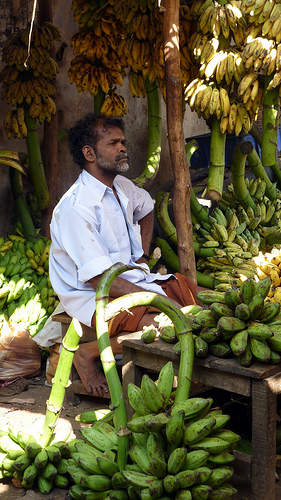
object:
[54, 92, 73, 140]
wall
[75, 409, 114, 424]
sandal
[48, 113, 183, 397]
man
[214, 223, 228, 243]
banana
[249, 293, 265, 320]
banana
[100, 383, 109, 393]
toes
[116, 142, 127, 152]
nose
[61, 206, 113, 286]
sleeves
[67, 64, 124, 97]
bunch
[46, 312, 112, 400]
stool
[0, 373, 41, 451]
ground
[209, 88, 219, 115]
banana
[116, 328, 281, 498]
table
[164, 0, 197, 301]
pole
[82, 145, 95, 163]
ear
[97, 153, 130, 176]
beard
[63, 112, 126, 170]
hair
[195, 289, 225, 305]
bananas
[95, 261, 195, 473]
stem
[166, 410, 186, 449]
banana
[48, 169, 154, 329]
fence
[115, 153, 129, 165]
mouth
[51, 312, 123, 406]
man seated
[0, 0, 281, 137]
bunchesofbanana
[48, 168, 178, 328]
shirt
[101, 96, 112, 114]
bananas